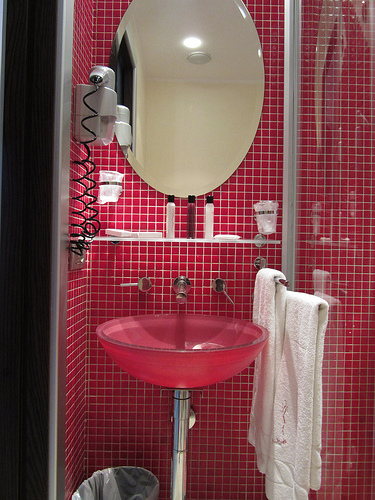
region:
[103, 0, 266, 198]
an oval mirror on the wall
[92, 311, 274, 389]
a rounded red sink basin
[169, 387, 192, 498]
a metal pipe beneath the sink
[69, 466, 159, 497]
a white trash bag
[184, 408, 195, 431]
a round metal piece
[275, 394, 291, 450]
a red design in a towel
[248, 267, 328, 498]
two white towels on hangers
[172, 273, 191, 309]
a metal silver faucet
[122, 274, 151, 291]
a metal handle for hot water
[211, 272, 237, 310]
a metal handle for cold water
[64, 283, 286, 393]
this sink is red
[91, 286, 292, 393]
the basin of the sink is red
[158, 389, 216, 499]
a silver pipe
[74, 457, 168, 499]
this is a trash can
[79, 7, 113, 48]
the wall is comprised of red square tiles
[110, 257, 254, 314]
the faucet and knobs of the sink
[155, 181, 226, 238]
three bottles of soap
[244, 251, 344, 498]
two white towels on rakcs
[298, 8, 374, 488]
part of the glass wall and door of a shower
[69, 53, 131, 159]
a white hair drier is mounted on the wall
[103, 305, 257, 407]
red sink bowl below faucet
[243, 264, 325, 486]
two white towels by sink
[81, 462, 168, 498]
trash can below sink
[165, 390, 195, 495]
chrome pipe below sink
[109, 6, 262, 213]
oval mirror above sink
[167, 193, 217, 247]
three product bottles above sink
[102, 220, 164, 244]
white bars of soap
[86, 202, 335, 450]
sink with red tile behind it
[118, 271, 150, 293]
left silver faucet handle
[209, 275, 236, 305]
right silver faucet handle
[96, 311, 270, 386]
a red glass sink bowl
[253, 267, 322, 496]
towels hanging on rack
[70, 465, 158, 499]
a trashcan with white bag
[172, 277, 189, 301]
water spout of sink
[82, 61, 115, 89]
a white hair dryer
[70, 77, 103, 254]
black spiral cord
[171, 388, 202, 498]
silver plumbing to sink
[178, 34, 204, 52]
lght reflection on mirror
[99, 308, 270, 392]
the sink in a bathroom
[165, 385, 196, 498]
the drainpipe of a sink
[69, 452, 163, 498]
a waste basket in a restroom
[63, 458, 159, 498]
the trash can in a bathroom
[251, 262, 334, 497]
two towels on racks in a bathroom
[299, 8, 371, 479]
the glass shower door in a bathroom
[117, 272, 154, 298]
the hot water knob to a sink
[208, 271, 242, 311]
the cold water knob to a sink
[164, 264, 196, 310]
the faucet of a sink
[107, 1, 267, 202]
a mirror in a bathroom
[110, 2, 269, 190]
a large oval mirror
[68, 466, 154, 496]
a plastic covered trash can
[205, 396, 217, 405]
a small red tile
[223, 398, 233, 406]
a small red tile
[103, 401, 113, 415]
a small red tile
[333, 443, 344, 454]
a small red tile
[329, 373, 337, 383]
a small red tile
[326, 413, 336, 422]
a small red tile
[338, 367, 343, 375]
a small red tile